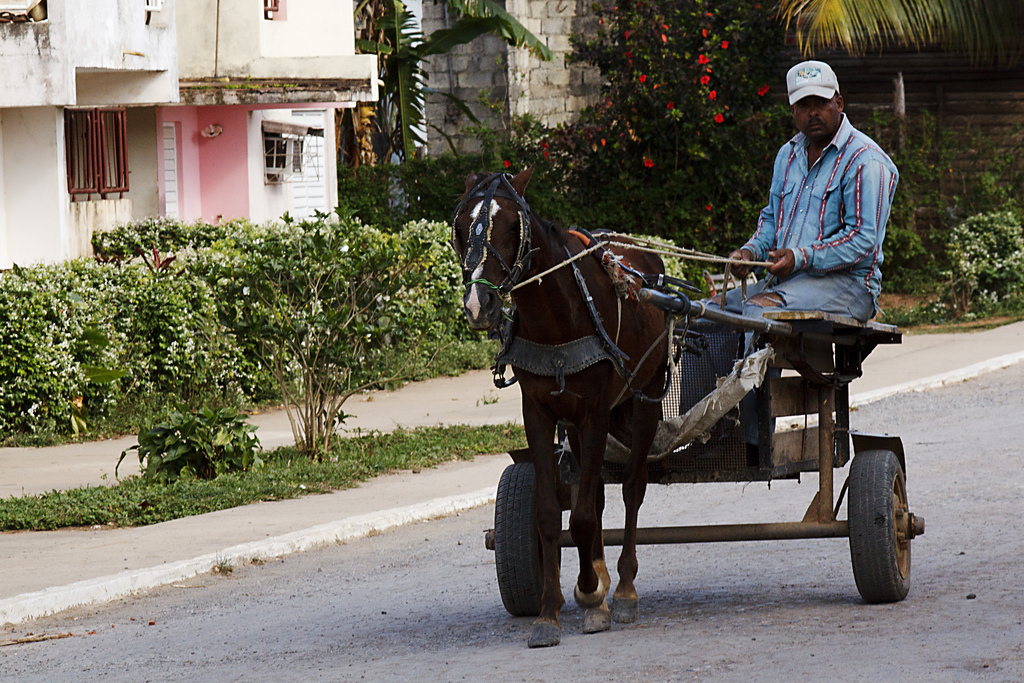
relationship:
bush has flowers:
[49, 241, 563, 441] [122, 337, 218, 362]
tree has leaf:
[337, 0, 594, 214] [404, 18, 565, 60]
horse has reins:
[385, 168, 667, 487] [534, 230, 641, 343]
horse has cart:
[385, 168, 667, 487] [653, 309, 904, 557]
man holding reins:
[704, 52, 899, 329] [534, 230, 641, 343]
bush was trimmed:
[49, 241, 563, 441] [100, 399, 244, 464]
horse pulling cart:
[385, 168, 667, 487] [653, 309, 904, 557]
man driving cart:
[704, 52, 899, 329] [653, 309, 904, 557]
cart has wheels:
[653, 309, 904, 557] [799, 436, 940, 594]